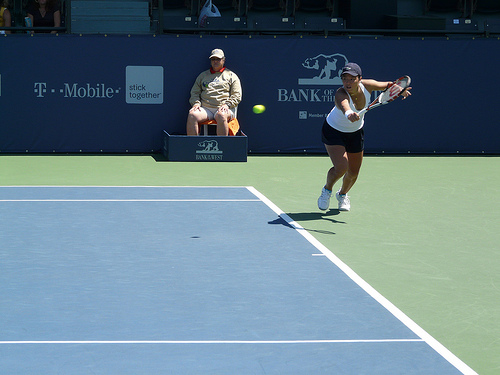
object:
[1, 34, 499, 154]
wall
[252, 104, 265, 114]
ball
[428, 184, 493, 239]
air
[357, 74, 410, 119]
racket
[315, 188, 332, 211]
shoes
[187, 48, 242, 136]
man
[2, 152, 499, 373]
court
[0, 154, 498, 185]
out-of-bounds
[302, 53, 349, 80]
bear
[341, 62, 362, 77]
hat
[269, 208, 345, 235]
shadow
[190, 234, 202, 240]
reflection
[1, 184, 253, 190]
line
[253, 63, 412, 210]
tennis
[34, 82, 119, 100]
banner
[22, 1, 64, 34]
fans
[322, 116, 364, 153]
shorts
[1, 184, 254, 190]
stripe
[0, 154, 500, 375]
ground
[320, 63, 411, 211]
lady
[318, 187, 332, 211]
feet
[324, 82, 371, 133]
shirt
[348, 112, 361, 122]
hands